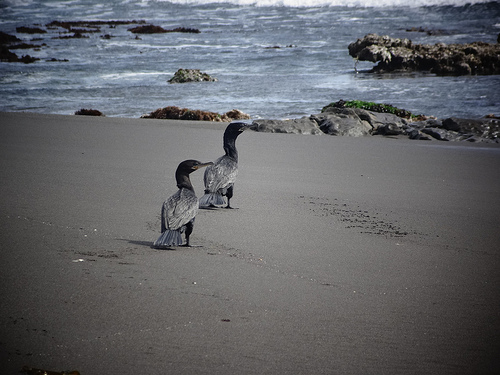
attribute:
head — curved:
[178, 157, 202, 174]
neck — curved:
[175, 173, 192, 190]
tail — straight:
[149, 229, 187, 251]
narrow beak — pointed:
[195, 151, 212, 185]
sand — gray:
[302, 190, 394, 230]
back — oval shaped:
[150, 190, 201, 247]